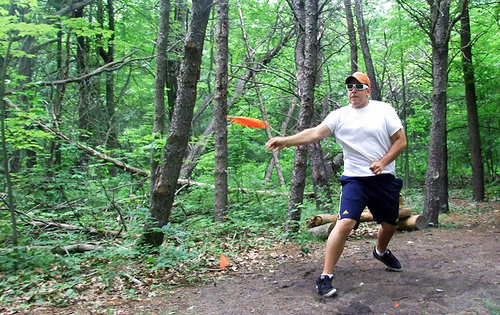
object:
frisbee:
[225, 115, 270, 129]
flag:
[218, 254, 231, 269]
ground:
[54, 206, 498, 315]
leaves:
[252, 253, 261, 259]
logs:
[305, 208, 412, 228]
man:
[265, 71, 408, 297]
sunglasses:
[346, 84, 369, 91]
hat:
[345, 71, 371, 90]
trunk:
[146, 137, 189, 215]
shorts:
[337, 173, 403, 226]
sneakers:
[316, 272, 338, 298]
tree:
[152, 0, 171, 254]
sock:
[321, 271, 334, 279]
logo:
[343, 209, 350, 215]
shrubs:
[4, 202, 179, 240]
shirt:
[324, 99, 405, 179]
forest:
[2, 5, 499, 315]